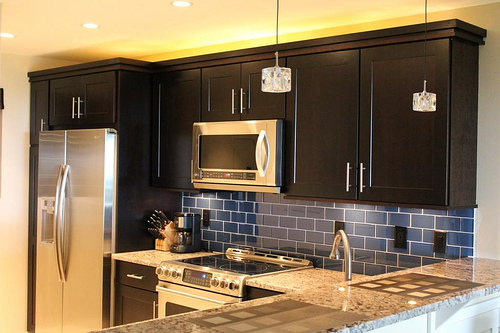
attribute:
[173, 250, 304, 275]
stove top — flat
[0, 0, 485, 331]
kitchen room — large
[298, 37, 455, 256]
cabinets — black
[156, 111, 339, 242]
microwave — silver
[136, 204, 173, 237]
knives — black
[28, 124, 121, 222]
fridge — silver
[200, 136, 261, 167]
window — black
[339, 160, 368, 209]
handles — silver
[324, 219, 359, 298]
faucet — silver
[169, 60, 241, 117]
cupboards — black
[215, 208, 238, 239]
tile — blue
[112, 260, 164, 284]
drawer — black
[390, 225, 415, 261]
outlets — black